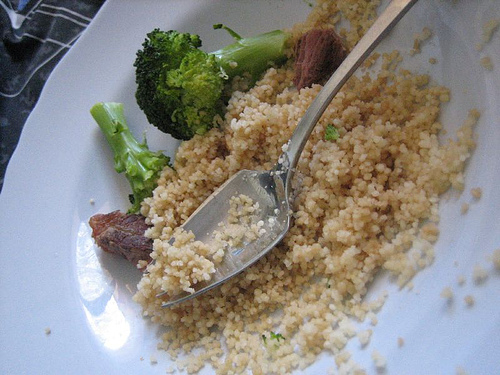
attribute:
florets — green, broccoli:
[129, 14, 300, 132]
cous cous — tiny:
[366, 311, 378, 326]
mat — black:
[0, 0, 113, 191]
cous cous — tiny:
[146, 224, 208, 304]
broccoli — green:
[130, 27, 263, 139]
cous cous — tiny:
[470, 185, 481, 200]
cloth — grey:
[3, 0, 103, 187]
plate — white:
[27, 172, 82, 344]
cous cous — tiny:
[150, 237, 210, 281]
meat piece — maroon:
[94, 202, 145, 262]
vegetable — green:
[81, 91, 183, 221]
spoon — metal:
[166, 2, 410, 299]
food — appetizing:
[96, 14, 446, 359]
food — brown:
[120, 32, 436, 329]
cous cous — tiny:
[315, 135, 415, 263]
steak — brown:
[90, 212, 150, 260]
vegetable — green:
[126, 24, 288, 139]